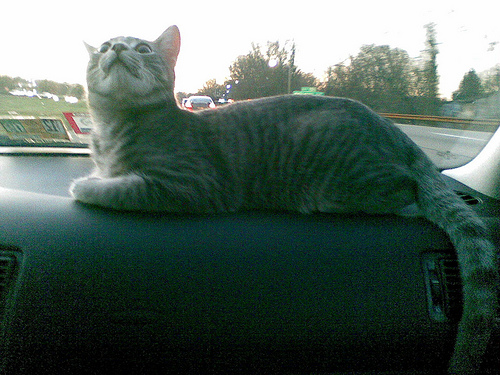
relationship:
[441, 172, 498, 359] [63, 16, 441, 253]
tail belongs to cat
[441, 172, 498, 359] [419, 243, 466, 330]
tail near air vent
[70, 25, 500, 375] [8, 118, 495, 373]
cat on top of car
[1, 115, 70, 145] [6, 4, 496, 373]
sticker on car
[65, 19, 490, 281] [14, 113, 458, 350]
cat in car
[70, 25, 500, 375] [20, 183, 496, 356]
cat sitting on car board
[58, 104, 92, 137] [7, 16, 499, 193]
decal on windshield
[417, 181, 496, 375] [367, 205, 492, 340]
tail over vent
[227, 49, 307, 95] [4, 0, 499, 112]
tree on background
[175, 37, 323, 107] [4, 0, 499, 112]
tree on background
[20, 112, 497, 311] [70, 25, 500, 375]
going for car ride with cat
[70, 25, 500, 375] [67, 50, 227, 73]
cat focused on something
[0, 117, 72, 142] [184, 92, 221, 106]
sticker for vehicle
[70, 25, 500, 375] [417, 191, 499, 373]
cat in cars tail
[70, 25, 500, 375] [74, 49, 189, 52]
cat looking up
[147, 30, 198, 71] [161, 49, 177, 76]
ear sticking up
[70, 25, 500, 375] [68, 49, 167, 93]
cat loking up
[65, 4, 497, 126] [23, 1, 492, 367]
daytime in photo